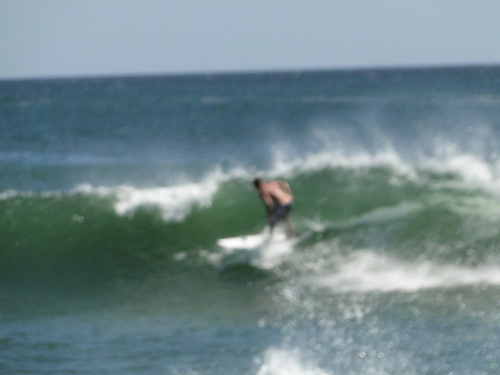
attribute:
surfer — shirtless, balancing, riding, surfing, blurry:
[246, 168, 299, 242]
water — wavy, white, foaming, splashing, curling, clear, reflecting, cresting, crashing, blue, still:
[1, 77, 499, 374]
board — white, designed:
[210, 226, 301, 256]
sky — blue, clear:
[0, 1, 499, 70]